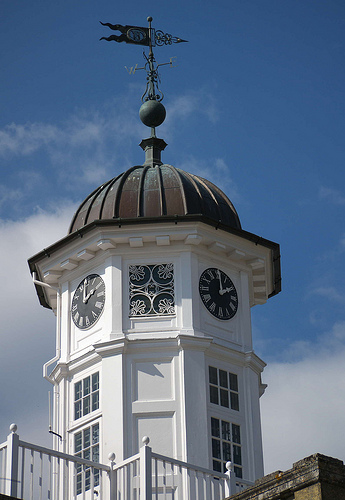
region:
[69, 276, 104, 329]
the black and white face of a clock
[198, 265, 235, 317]
the black and white face of a clock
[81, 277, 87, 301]
the white hand of a clock face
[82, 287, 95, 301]
the white hand of a clock face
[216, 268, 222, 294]
the white hand of a clock face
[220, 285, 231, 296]
the white hand of a clock face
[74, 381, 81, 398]
the small window pane of a window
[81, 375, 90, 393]
the small window pane of a window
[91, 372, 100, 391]
the small window pane of a window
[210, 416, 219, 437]
the small window pane of a window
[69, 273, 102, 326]
the black and white clock face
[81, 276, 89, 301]
the white clock hand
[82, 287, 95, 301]
the white clock hand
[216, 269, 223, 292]
the white clock hand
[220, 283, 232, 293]
the white clock hand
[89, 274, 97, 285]
the white roman numeral I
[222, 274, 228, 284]
the white roman numeral I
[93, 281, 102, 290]
the white roman numeral II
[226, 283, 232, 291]
the white roman numeral II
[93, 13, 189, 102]
metal weather vain on top of a building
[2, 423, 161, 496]
White fence around the top of clock tower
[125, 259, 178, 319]
decorative pattern on the outside of the building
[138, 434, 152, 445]
white ball on top of the fence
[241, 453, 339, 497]
edge of building is brick and brown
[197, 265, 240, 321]
clock face is black with white hands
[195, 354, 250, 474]
side window facing the the shade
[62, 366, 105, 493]
windows facing the sun on top of building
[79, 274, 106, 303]
the time is showing 2:00 on the clock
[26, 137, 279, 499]
A clock tower on top of a building.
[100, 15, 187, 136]
A weather vane with an arrow on top of a pole.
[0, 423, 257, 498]
White fence around the tower balcony.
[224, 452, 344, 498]
Concrete edge of a building.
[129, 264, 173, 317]
A window with white floral designs.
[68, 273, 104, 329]
Round black clock face.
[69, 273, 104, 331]
White numbers and hands on the clock face.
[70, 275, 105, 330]
Roman numerals on the clock.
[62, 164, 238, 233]
A dome at the top of the tower.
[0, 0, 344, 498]
Blue sky with clouds.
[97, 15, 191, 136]
a green patina weather vane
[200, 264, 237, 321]
a black and white clock face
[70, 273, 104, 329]
a black and white clock face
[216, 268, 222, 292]
a white clock face minute hand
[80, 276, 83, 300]
a white clock face minute hand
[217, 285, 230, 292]
a white clock face hour hand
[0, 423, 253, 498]
a white wood fence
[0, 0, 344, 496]
a cloudy blue sky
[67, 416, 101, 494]
a large 9 paned window